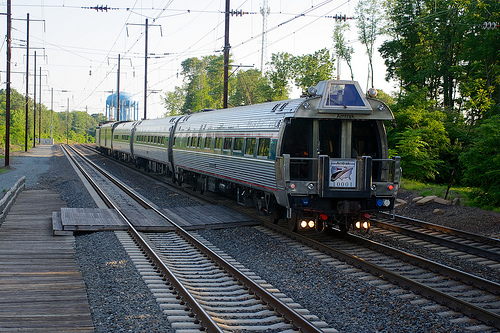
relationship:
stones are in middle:
[99, 159, 179, 207] [120, 165, 364, 314]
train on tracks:
[93, 80, 405, 236] [371, 223, 492, 314]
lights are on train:
[299, 214, 374, 235] [93, 80, 405, 236]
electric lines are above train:
[15, 0, 363, 93] [93, 80, 405, 236]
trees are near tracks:
[171, 54, 343, 96] [371, 223, 492, 314]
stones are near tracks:
[99, 159, 179, 207] [371, 223, 492, 314]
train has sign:
[93, 80, 405, 236] [330, 155, 357, 189]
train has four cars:
[93, 80, 405, 236] [96, 120, 287, 203]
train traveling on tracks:
[93, 80, 405, 236] [371, 223, 492, 314]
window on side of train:
[252, 132, 272, 157] [93, 80, 405, 236]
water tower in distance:
[99, 92, 144, 120] [13, 26, 154, 132]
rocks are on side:
[80, 233, 129, 330] [28, 138, 107, 331]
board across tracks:
[41, 202, 259, 236] [82, 181, 248, 301]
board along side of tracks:
[41, 202, 259, 236] [82, 181, 248, 301]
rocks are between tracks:
[80, 233, 129, 330] [82, 181, 248, 301]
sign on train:
[330, 155, 357, 189] [93, 80, 405, 236]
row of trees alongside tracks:
[0, 86, 116, 150] [82, 181, 248, 301]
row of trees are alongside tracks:
[0, 86, 116, 150] [82, 181, 248, 301]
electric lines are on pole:
[15, 0, 363, 93] [215, 0, 238, 112]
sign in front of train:
[330, 155, 357, 189] [93, 80, 405, 236]